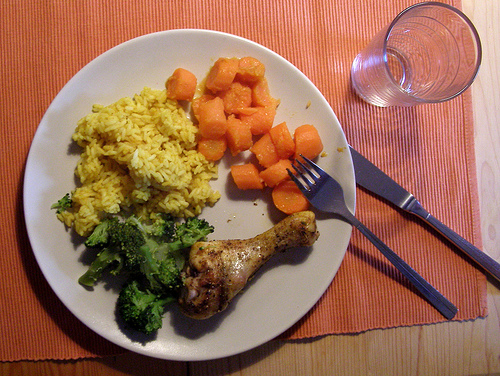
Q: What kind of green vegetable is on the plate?
A: Broccoli.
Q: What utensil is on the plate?
A: Fork.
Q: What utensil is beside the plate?
A: Knife.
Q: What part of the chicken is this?
A: Leg.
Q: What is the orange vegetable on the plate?
A: Carrots.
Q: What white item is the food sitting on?
A: Plate.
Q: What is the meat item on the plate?
A: Chicken.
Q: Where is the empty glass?
A: On the orange placemat?.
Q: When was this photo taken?
A: Before a meal.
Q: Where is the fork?
A: On the white plate.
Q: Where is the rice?
A: On the white plate next to the carrots.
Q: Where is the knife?
A: On the orange placemat.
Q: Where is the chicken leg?
A: Next to the broccoli and carrots.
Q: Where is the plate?
A: Sitting on a table.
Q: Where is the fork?
A: By the carrots and the chicken.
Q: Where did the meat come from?
A: A chicken.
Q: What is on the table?
A: A plate of food.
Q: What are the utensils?
A: A fork and knife.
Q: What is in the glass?
A: The glass is empty.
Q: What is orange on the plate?
A: Carrots.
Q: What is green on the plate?
A: Broccoli.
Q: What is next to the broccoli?
A: Rice.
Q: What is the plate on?
A: A cloth placemat.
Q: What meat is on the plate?
A: A chicken leg.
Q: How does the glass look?
A: Clear.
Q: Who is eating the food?
A: One person.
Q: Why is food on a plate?
A: To be eaten.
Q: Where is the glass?
A: On a placemat.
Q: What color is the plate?
A: White.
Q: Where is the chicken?
A: On the plate.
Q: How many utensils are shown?
A: 2.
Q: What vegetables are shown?
A: Carrots and broccoli.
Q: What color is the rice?
A: Yellow.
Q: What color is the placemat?
A: Pink.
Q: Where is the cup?
A: Above the plate.